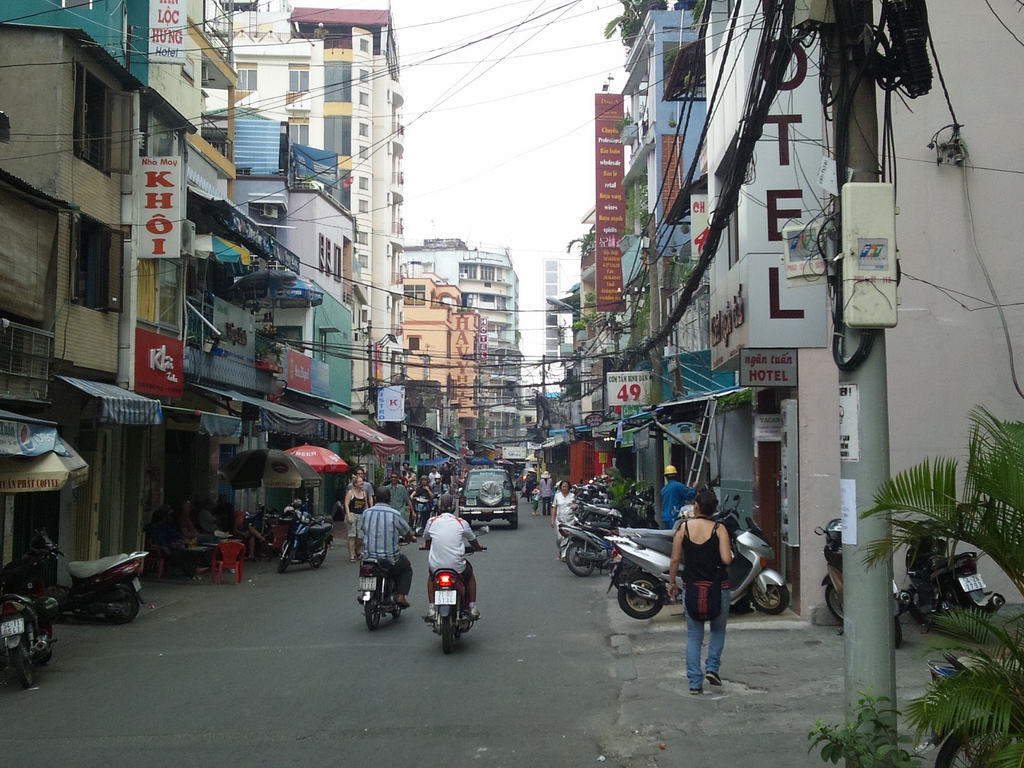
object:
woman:
[674, 490, 731, 697]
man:
[355, 490, 414, 613]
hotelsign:
[737, 345, 800, 388]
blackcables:
[278, 334, 620, 372]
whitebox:
[838, 178, 899, 330]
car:
[458, 468, 521, 528]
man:
[419, 490, 481, 632]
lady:
[665, 493, 732, 690]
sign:
[130, 155, 182, 256]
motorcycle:
[358, 528, 411, 627]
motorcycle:
[603, 510, 778, 619]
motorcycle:
[6, 535, 147, 624]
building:
[605, 1, 1016, 584]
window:
[67, 223, 119, 305]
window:
[78, 73, 114, 167]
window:
[161, 265, 181, 326]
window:
[140, 252, 161, 323]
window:
[236, 71, 259, 93]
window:
[291, 73, 309, 93]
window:
[289, 124, 310, 146]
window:
[320, 234, 325, 272]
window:
[325, 238, 331, 276]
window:
[361, 72, 370, 85]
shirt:
[422, 508, 471, 580]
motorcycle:
[414, 565, 477, 652]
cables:
[25, 7, 569, 158]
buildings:
[396, 240, 512, 411]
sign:
[591, 89, 628, 316]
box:
[835, 181, 899, 334]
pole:
[828, 11, 901, 759]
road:
[124, 484, 607, 768]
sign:
[740, 25, 832, 350]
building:
[225, 33, 400, 150]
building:
[7, 70, 527, 538]